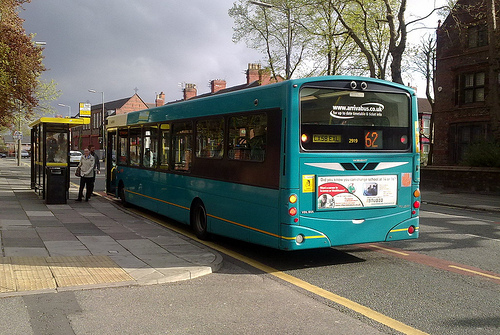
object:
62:
[363, 130, 381, 149]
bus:
[100, 75, 421, 254]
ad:
[314, 175, 396, 213]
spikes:
[242, 68, 246, 75]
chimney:
[243, 61, 261, 85]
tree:
[378, 0, 418, 87]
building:
[420, 0, 500, 197]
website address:
[327, 100, 386, 120]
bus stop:
[29, 114, 89, 206]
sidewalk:
[0, 156, 220, 297]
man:
[74, 148, 97, 201]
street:
[16, 150, 498, 333]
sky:
[0, 2, 452, 122]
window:
[471, 84, 485, 102]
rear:
[288, 73, 418, 251]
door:
[103, 131, 118, 199]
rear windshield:
[298, 84, 411, 127]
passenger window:
[126, 126, 141, 167]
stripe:
[96, 194, 421, 334]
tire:
[185, 198, 211, 239]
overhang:
[27, 115, 90, 128]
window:
[140, 127, 158, 169]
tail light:
[286, 206, 296, 216]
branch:
[404, 6, 448, 28]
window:
[172, 118, 193, 173]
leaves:
[28, 31, 39, 39]